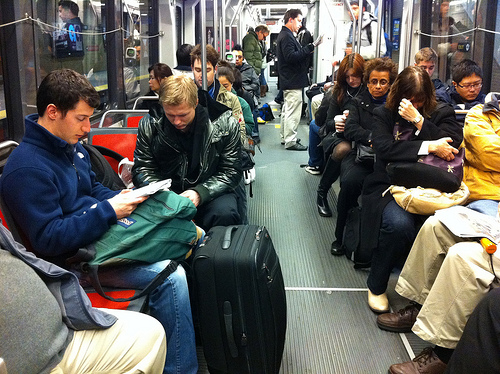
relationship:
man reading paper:
[1, 68, 200, 373] [89, 178, 173, 201]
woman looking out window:
[141, 64, 173, 109] [111, 0, 155, 107]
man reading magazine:
[1, 68, 200, 373] [89, 178, 173, 201]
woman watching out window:
[141, 64, 173, 109] [111, 0, 155, 107]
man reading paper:
[275, 9, 314, 153] [310, 34, 322, 47]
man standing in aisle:
[275, 9, 314, 153] [247, 85, 410, 373]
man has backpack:
[1, 68, 200, 373] [77, 189, 197, 304]